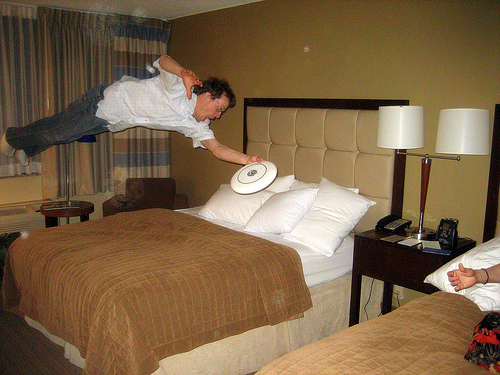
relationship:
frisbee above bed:
[231, 165, 291, 196] [12, 164, 350, 335]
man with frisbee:
[0, 36, 246, 190] [231, 165, 291, 196]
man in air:
[0, 36, 246, 190] [38, 7, 325, 168]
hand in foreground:
[198, 131, 282, 196] [4, 32, 354, 274]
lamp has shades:
[350, 71, 498, 173] [289, 97, 428, 155]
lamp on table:
[350, 71, 498, 173] [322, 208, 480, 301]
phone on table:
[374, 213, 413, 236] [322, 208, 480, 301]